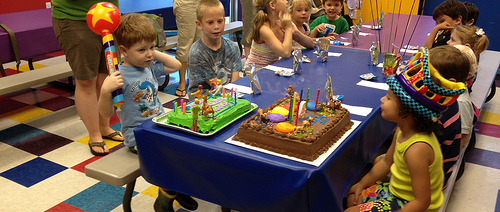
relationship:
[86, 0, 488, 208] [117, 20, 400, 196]
children sitting at table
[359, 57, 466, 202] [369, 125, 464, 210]
child wearing shirt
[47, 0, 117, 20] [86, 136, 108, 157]
shirt with flip flop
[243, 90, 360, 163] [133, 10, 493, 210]
cakes on table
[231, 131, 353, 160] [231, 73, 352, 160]
icing on cake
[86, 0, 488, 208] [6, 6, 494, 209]
children attending party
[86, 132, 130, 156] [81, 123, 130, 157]
sandals on feet